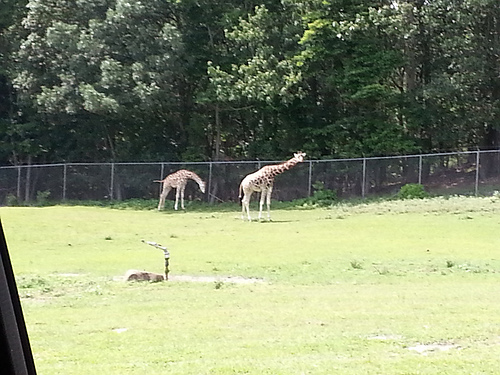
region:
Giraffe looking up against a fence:
[237, 147, 322, 227]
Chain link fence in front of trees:
[317, 150, 479, 197]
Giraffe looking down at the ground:
[148, 167, 211, 214]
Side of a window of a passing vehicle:
[2, 188, 47, 373]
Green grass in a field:
[303, 221, 438, 258]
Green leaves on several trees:
[15, 18, 190, 118]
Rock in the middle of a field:
[118, 261, 175, 306]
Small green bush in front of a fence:
[388, 177, 436, 207]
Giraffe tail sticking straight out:
[149, 176, 167, 186]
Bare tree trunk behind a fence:
[209, 92, 228, 210]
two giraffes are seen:
[160, 174, 280, 209]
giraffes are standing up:
[158, 174, 287, 218]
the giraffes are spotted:
[152, 162, 289, 226]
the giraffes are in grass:
[147, 172, 299, 229]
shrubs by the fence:
[280, 194, 378, 207]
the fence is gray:
[308, 157, 395, 187]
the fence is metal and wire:
[305, 157, 429, 189]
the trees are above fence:
[276, 22, 423, 204]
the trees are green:
[189, 5, 471, 100]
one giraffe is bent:
[154, 167, 214, 227]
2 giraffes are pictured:
[93, 121, 498, 297]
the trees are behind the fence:
[11, 7, 476, 198]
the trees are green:
[20, 10, 495, 205]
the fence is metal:
[51, 140, 498, 266]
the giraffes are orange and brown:
[158, 144, 493, 329]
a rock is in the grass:
[86, 229, 176, 343]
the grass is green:
[46, 221, 273, 348]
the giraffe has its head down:
[138, 158, 225, 250]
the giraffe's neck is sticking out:
[223, 141, 368, 230]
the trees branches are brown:
[396, 8, 484, 142]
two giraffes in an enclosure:
[158, 147, 310, 218]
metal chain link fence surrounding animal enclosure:
[314, 147, 499, 212]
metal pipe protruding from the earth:
[137, 235, 178, 295]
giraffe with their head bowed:
[151, 167, 211, 215]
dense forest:
[36, 6, 456, 137]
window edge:
[2, 237, 51, 374]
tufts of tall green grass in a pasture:
[345, 250, 480, 281]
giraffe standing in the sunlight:
[229, 147, 310, 228]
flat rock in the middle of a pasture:
[121, 263, 162, 290]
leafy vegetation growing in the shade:
[301, 182, 464, 209]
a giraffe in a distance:
[228, 141, 308, 228]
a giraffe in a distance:
[153, 166, 212, 222]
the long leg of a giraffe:
[266, 186, 273, 216]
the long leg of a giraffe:
[257, 185, 264, 220]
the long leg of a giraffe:
[244, 195, 252, 216]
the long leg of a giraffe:
[241, 195, 247, 216]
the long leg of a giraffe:
[173, 185, 179, 212]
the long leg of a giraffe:
[178, 186, 187, 208]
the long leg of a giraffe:
[159, 189, 164, 210]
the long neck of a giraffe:
[188, 170, 202, 186]